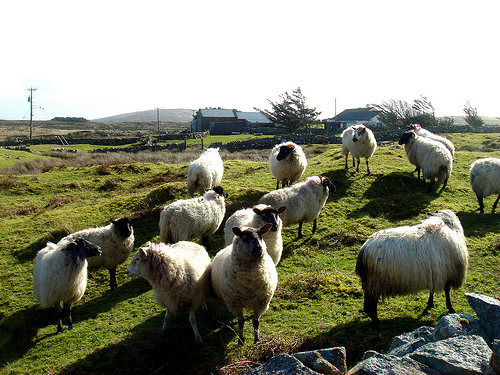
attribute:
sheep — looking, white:
[127, 203, 285, 346]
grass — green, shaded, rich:
[39, 330, 89, 361]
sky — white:
[323, 9, 457, 63]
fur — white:
[175, 204, 214, 229]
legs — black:
[234, 306, 260, 346]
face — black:
[241, 230, 266, 257]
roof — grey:
[331, 107, 382, 121]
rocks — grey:
[247, 291, 500, 374]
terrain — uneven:
[1, 122, 301, 163]